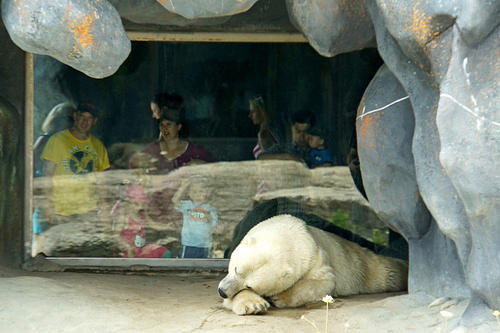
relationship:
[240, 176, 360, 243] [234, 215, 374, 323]
blanket covering polar bear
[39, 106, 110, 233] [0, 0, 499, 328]
man looking into cage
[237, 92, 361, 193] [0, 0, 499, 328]
people looking into cage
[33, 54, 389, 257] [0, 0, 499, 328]
window on cage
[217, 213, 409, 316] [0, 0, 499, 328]
bear in cage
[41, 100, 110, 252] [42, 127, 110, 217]
man wearing t-shirt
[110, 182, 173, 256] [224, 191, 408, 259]
child looking into cave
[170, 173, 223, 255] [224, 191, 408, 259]
child looking into cave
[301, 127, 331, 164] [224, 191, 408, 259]
child looking into cave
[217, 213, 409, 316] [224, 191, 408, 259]
bear in cave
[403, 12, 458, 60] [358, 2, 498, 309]
yellow paint on rocks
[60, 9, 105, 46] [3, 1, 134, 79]
yellow paint on rocks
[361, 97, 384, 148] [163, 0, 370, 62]
yellow paint on rocks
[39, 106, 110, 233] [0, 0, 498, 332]
man in zoo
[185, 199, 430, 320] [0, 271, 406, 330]
bear on floor